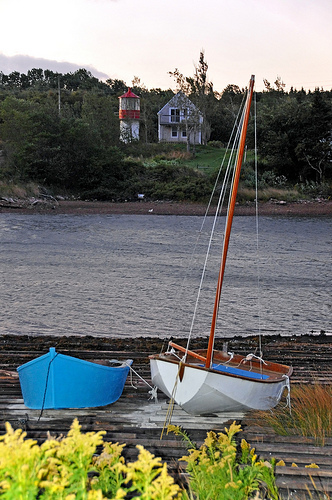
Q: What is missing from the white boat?
A: Sail.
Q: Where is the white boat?
A: Beside blue boat.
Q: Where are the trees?
A: Beside water.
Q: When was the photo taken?
A: Dull day.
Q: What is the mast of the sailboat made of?
A: Wood.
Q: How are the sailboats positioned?
A: Next to each other.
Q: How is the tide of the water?
A: Low.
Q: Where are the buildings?
A: In background.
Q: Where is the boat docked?
A: Along the river.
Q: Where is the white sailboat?
A: Beside the blue boat.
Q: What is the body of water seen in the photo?
A: A river.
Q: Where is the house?
A: Across the river.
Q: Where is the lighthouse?
A: Beside the house.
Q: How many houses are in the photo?
A: Two.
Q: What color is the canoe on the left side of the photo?
A: Blue.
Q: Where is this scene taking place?
A: Close to the river.